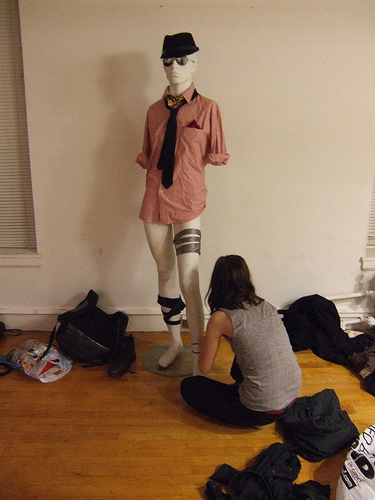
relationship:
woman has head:
[136, 203, 349, 445] [166, 238, 287, 340]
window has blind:
[5, 68, 30, 232] [2, 148, 24, 174]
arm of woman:
[181, 315, 228, 398] [136, 203, 349, 445]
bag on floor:
[338, 415, 374, 488] [59, 384, 182, 498]